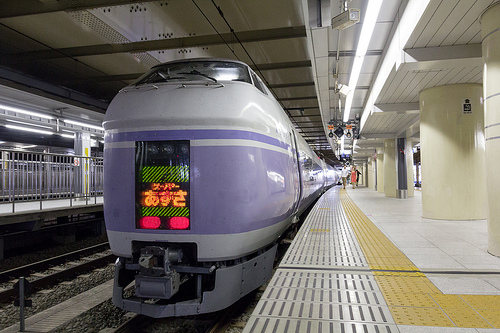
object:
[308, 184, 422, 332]
platform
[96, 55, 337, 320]
train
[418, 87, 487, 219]
pillar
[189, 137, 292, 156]
stripe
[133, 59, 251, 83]
windshield